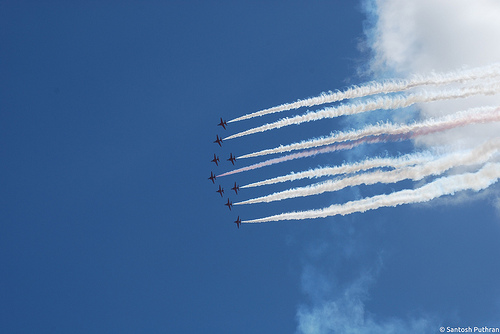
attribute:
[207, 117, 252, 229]
jets — moving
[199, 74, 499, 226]
air show — live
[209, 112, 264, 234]
jet — leaving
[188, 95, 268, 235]
jets — flying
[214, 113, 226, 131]
plane — flying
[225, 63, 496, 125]
contrail — pink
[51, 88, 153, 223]
sky — clear, blue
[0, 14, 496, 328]
sky — clear, dark, blue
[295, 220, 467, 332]
clouds — fluffy, white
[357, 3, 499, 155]
cloud — large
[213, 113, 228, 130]
airplanes — together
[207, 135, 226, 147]
airplanes — together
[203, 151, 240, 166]
airplanes — together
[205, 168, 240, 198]
airplanes — together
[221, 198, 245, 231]
airplanes — together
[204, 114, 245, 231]
planes — flying